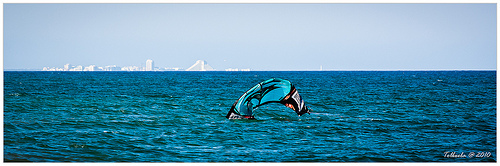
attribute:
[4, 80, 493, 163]
water — dark, bluish green, blue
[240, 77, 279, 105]
pattern — black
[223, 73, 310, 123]
kite — curved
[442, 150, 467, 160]
letter — white, print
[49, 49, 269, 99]
building — white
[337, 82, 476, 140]
waves — calm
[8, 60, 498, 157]
water — blue and green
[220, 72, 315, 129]
sail — wind, hanging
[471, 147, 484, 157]
number — white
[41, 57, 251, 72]
buildings — white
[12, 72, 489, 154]
water — very contrasting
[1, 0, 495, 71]
sky — bright, blue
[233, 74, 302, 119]
pattern — turquoise blue, geometric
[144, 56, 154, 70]
tower — white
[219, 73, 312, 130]
parachute — blue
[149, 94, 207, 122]
wavy — blue, ocean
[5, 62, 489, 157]
ocean water — wavy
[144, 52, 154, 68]
building — tall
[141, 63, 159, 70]
building — by itself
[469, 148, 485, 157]
number — white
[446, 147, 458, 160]
letter — white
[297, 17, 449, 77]
sky — hazy, light blue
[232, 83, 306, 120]
sail — wind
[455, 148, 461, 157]
letter — white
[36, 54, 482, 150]
water — deep, blue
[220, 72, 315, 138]
sport — water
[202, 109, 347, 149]
landing — safe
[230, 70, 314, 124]
sail — wind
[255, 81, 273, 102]
markings — black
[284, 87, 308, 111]
print — white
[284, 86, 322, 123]
letter — white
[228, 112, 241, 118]
corner — white